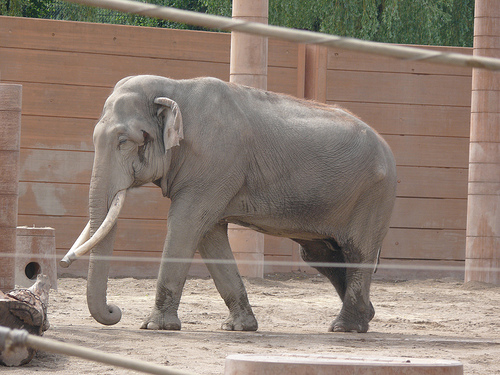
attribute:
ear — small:
[148, 94, 187, 151]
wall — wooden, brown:
[0, 27, 483, 277]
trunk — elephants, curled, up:
[84, 158, 123, 325]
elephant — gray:
[87, 74, 398, 331]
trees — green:
[4, 0, 479, 56]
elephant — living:
[60, 62, 411, 357]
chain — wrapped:
[13, 285, 48, 323]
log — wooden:
[0, 272, 52, 368]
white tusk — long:
[50, 202, 123, 259]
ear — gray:
[146, 93, 193, 150]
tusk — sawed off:
[61, 212, 91, 270]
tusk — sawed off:
[72, 191, 129, 265]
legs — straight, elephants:
[138, 199, 264, 336]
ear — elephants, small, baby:
[150, 94, 189, 154]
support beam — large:
[228, 1, 268, 276]